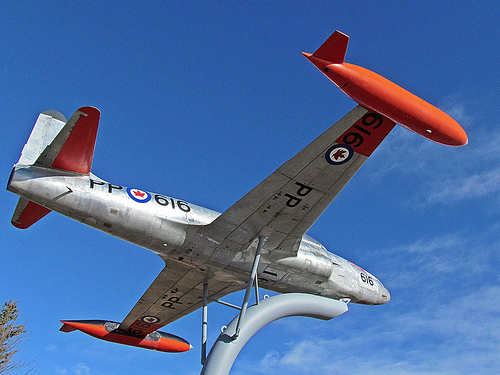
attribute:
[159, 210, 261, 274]
plane — orange, big, silver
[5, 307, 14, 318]
leaf — brown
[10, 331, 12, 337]
leaf — brown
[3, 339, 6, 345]
leaf — brown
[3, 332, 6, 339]
leaf — brown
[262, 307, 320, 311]
beam — metal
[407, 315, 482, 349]
cloud — white